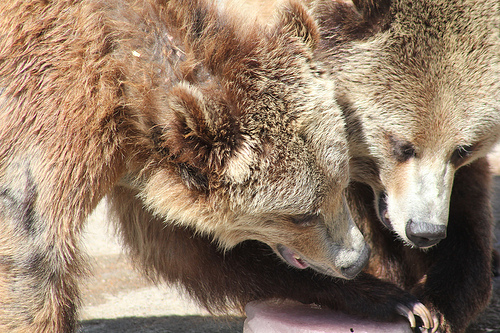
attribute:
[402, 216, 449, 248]
nose — bear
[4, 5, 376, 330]
bear — larger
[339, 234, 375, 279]
nose — black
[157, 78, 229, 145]
ear — brown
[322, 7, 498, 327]
bear — brown, white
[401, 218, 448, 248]
nose — black